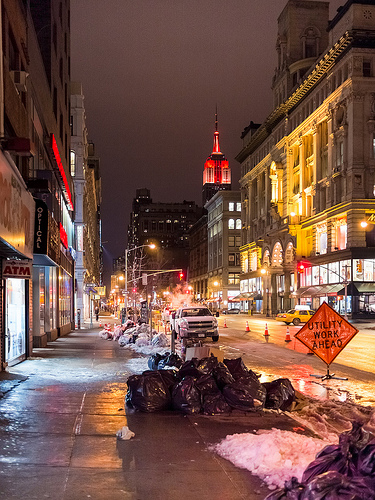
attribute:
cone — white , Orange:
[245, 317, 251, 331]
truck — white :
[170, 305, 218, 356]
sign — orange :
[291, 295, 356, 368]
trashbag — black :
[259, 378, 293, 411]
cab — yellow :
[273, 302, 316, 327]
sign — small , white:
[0, 260, 35, 281]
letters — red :
[0, 264, 28, 275]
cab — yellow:
[273, 307, 316, 326]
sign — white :
[293, 301, 359, 364]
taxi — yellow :
[276, 308, 313, 324]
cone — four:
[219, 315, 228, 328]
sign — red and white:
[3, 263, 34, 280]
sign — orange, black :
[289, 297, 362, 377]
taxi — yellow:
[275, 305, 316, 328]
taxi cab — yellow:
[273, 303, 313, 328]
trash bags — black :
[118, 344, 294, 429]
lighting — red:
[251, 148, 313, 237]